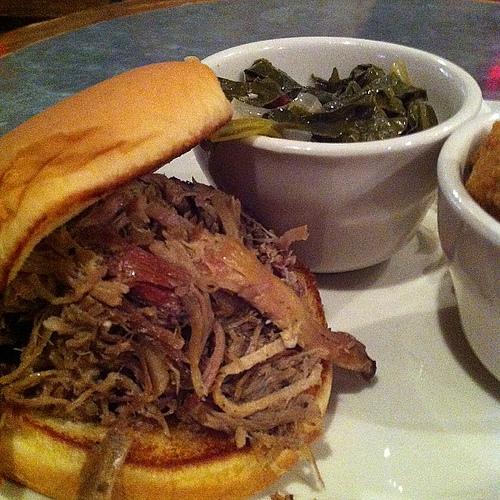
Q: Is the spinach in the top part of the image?
A: Yes, the spinach is in the top of the image.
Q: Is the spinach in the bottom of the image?
A: No, the spinach is in the top of the image.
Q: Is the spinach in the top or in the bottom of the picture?
A: The spinach is in the top of the image.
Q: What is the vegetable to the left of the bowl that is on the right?
A: The vegetable is spinach.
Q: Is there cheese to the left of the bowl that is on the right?
A: No, there is spinach to the left of the bowl.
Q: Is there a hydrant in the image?
A: No, there are no fire hydrants.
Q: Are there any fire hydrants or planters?
A: No, there are no fire hydrants or planters.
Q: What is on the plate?
A: The bowl is on the plate.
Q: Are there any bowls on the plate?
A: Yes, there is a bowl on the plate.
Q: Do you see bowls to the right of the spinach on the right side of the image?
A: Yes, there is a bowl to the right of the spinach.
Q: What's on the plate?
A: The bowl is on the plate.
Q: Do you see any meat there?
A: Yes, there is meat.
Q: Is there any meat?
A: Yes, there is meat.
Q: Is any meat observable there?
A: Yes, there is meat.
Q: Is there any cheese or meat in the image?
A: Yes, there is meat.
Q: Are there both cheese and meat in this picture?
A: No, there is meat but no cheese.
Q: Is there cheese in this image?
A: No, there is no cheese.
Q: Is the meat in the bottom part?
A: Yes, the meat is in the bottom of the image.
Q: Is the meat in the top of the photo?
A: No, the meat is in the bottom of the image.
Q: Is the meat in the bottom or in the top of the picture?
A: The meat is in the bottom of the image.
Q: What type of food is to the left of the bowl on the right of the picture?
A: The food is meat.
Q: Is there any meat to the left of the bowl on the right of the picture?
A: Yes, there is meat to the left of the bowl.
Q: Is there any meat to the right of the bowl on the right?
A: No, the meat is to the left of the bowl.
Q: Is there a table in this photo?
A: Yes, there is a table.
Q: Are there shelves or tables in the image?
A: Yes, there is a table.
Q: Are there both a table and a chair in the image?
A: No, there is a table but no chairs.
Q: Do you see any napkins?
A: No, there are no napkins.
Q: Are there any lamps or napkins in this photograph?
A: No, there are no napkins or lamps.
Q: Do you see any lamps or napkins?
A: No, there are no napkins or lamps.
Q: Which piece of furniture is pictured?
A: The piece of furniture is a table.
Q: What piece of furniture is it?
A: The piece of furniture is a table.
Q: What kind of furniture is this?
A: That is a table.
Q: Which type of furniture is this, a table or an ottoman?
A: That is a table.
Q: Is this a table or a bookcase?
A: This is a table.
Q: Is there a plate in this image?
A: Yes, there is a plate.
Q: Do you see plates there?
A: Yes, there is a plate.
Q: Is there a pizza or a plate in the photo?
A: Yes, there is a plate.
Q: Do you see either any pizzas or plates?
A: Yes, there is a plate.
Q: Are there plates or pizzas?
A: Yes, there is a plate.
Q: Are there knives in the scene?
A: No, there are no knives.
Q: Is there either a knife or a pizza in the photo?
A: No, there are no knives or pizzas.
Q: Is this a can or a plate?
A: This is a plate.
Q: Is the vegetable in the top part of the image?
A: Yes, the vegetable is in the top of the image.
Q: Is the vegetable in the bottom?
A: No, the vegetable is in the top of the image.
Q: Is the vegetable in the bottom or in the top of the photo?
A: The vegetable is in the top of the image.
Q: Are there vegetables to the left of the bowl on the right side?
A: Yes, there is a vegetable to the left of the bowl.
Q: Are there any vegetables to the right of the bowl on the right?
A: No, the vegetable is to the left of the bowl.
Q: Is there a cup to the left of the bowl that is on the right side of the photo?
A: No, there is a vegetable to the left of the bowl.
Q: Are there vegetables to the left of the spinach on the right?
A: Yes, there is a vegetable to the left of the spinach.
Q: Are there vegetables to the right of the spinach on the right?
A: No, the vegetable is to the left of the spinach.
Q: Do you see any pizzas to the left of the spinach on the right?
A: No, there is a vegetable to the left of the spinach.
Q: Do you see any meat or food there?
A: Yes, there is meat.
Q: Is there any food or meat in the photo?
A: Yes, there is meat.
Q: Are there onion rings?
A: No, there are no onion rings.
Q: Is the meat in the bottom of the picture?
A: Yes, the meat is in the bottom of the image.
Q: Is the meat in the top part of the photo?
A: No, the meat is in the bottom of the image.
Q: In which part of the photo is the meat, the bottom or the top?
A: The meat is in the bottom of the image.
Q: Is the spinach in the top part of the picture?
A: Yes, the spinach is in the top of the image.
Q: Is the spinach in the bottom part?
A: No, the spinach is in the top of the image.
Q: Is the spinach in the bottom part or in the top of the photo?
A: The spinach is in the top of the image.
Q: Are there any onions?
A: Yes, there is an onion.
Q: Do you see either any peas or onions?
A: Yes, there is an onion.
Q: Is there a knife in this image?
A: No, there are no knives.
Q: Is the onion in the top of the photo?
A: Yes, the onion is in the top of the image.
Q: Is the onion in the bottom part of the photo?
A: No, the onion is in the top of the image.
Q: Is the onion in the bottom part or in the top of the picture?
A: The onion is in the top of the image.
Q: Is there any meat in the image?
A: Yes, there is meat.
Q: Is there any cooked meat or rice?
A: Yes, there is cooked meat.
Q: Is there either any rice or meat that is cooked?
A: Yes, the meat is cooked.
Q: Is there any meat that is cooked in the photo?
A: Yes, there is cooked meat.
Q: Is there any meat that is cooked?
A: Yes, there is meat that is cooked.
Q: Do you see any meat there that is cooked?
A: Yes, there is meat that is cooked.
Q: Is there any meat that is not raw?
A: Yes, there is cooked meat.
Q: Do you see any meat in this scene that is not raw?
A: Yes, there is cooked meat.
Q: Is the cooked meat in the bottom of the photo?
A: Yes, the meat is in the bottom of the image.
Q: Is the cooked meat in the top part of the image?
A: No, the meat is in the bottom of the image.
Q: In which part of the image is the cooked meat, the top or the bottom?
A: The meat is in the bottom of the image.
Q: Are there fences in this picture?
A: No, there are no fences.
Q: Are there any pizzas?
A: No, there are no pizzas.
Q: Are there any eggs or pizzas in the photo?
A: No, there are no pizzas or eggs.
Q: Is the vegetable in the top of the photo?
A: Yes, the vegetable is in the top of the image.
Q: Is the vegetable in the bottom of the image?
A: No, the vegetable is in the top of the image.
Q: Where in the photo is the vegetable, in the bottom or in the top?
A: The vegetable is in the top of the image.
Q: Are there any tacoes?
A: No, there are no tacoes.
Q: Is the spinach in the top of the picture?
A: Yes, the spinach is in the top of the image.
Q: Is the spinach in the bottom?
A: No, the spinach is in the top of the image.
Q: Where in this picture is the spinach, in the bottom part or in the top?
A: The spinach is in the top of the image.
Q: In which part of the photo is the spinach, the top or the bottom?
A: The spinach is in the top of the image.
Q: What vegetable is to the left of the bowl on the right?
A: The vegetable is spinach.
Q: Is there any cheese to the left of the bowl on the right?
A: No, there is spinach to the left of the bowl.